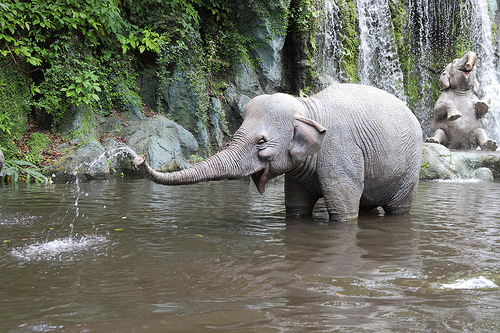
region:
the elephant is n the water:
[109, 77, 438, 226]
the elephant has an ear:
[285, 109, 330, 172]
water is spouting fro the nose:
[96, 145, 146, 170]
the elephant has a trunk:
[154, 157, 231, 182]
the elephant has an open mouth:
[245, 163, 272, 194]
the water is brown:
[119, 242, 200, 289]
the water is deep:
[311, 230, 418, 260]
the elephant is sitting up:
[424, 47, 495, 153]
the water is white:
[472, 10, 498, 55]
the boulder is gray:
[425, 140, 460, 189]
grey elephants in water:
[131, 51, 499, 224]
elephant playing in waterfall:
[426, 44, 496, 151]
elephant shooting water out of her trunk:
[24, 137, 155, 263]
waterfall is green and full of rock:
[296, 0, 499, 182]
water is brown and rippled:
[0, 170, 499, 331]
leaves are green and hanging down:
[0, 1, 256, 164]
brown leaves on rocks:
[13, 106, 170, 183]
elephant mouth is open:
[248, 169, 267, 196]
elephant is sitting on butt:
[420, 52, 499, 156]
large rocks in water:
[414, 144, 499, 184]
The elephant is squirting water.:
[107, 136, 166, 191]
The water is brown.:
[166, 239, 343, 331]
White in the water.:
[13, 220, 124, 265]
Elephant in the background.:
[428, 45, 491, 165]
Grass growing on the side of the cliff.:
[338, 10, 464, 86]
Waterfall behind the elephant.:
[433, 5, 499, 115]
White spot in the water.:
[436, 263, 499, 300]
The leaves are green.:
[13, 4, 159, 89]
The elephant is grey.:
[223, 80, 440, 203]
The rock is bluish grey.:
[63, 104, 215, 159]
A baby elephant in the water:
[149, 97, 443, 252]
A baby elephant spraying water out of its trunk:
[58, 98, 406, 275]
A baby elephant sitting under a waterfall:
[392, 37, 482, 145]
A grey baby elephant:
[152, 91, 437, 226]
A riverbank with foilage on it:
[76, 10, 451, 90]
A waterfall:
[377, 0, 483, 203]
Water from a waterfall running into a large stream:
[345, 11, 492, 289]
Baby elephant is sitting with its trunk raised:
[418, 47, 488, 155]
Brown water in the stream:
[45, 218, 416, 308]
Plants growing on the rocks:
[164, 9, 232, 121]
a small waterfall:
[18, 9, 493, 331]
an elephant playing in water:
[94, 54, 434, 256]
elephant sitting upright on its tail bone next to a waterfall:
[430, 36, 494, 192]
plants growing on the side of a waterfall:
[47, 33, 473, 91]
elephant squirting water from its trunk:
[28, 93, 333, 204]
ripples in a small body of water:
[294, 233, 454, 323]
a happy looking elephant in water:
[90, 66, 458, 236]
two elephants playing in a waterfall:
[185, 13, 490, 256]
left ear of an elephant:
[285, 97, 329, 181]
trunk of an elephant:
[96, 113, 303, 231]